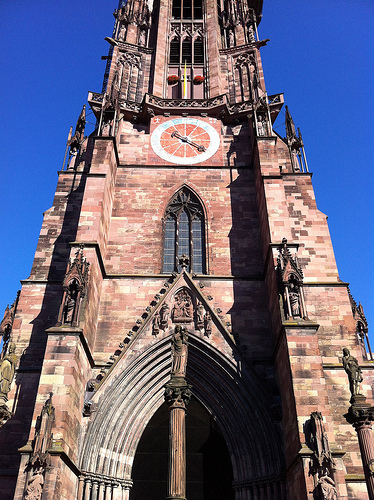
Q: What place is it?
A: It is a church.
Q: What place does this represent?
A: It represents the church.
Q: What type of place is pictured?
A: It is a church.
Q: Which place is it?
A: It is a church.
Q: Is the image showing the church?
A: Yes, it is showing the church.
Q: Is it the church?
A: Yes, it is the church.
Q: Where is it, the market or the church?
A: It is the church.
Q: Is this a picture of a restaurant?
A: No, the picture is showing a church.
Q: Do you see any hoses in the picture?
A: No, there are no hoses.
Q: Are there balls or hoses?
A: No, there are no hoses or balls.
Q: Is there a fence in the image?
A: No, there are no fences.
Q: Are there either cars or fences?
A: No, there are no fences or cars.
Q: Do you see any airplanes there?
A: No, there are no airplanes.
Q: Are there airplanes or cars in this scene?
A: No, there are no airplanes or cars.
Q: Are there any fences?
A: No, there are no fences.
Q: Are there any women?
A: Yes, there is a woman.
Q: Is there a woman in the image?
A: Yes, there is a woman.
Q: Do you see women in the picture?
A: Yes, there is a woman.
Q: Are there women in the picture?
A: Yes, there is a woman.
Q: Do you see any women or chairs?
A: Yes, there is a woman.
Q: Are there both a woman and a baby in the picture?
A: No, there is a woman but no babies.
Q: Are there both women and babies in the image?
A: No, there is a woman but no babies.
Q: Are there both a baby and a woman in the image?
A: No, there is a woman but no babies.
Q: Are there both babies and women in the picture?
A: No, there is a woman but no babies.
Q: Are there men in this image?
A: No, there are no men.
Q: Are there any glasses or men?
A: No, there are no men or glasses.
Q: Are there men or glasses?
A: No, there are no men or glasses.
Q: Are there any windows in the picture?
A: Yes, there is a window.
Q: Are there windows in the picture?
A: Yes, there is a window.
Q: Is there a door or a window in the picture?
A: Yes, there is a window.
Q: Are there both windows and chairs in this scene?
A: No, there is a window but no chairs.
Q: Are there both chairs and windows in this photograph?
A: No, there is a window but no chairs.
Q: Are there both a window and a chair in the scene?
A: No, there is a window but no chairs.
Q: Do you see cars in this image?
A: No, there are no cars.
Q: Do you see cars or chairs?
A: No, there are no cars or chairs.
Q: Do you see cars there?
A: No, there are no cars.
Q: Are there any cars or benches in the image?
A: No, there are no cars or benches.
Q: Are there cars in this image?
A: No, there are no cars.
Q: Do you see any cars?
A: No, there are no cars.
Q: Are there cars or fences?
A: No, there are no cars or fences.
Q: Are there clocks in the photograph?
A: Yes, there is a clock.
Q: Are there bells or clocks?
A: Yes, there is a clock.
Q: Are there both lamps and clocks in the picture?
A: No, there is a clock but no lamps.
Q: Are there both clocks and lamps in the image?
A: No, there is a clock but no lamps.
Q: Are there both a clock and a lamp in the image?
A: No, there is a clock but no lamps.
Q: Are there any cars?
A: No, there are no cars.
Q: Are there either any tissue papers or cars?
A: No, there are no cars or tissue papers.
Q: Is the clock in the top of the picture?
A: Yes, the clock is in the top of the image.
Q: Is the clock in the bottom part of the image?
A: No, the clock is in the top of the image.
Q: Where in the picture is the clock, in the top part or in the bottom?
A: The clock is in the top of the image.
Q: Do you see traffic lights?
A: No, there are no traffic lights.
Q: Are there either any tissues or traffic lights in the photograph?
A: No, there are no traffic lights or tissues.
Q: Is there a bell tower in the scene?
A: Yes, there is a bell tower.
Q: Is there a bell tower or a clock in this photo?
A: Yes, there is a bell tower.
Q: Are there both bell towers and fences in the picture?
A: No, there is a bell tower but no fences.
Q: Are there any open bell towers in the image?
A: Yes, there is an open bell tower.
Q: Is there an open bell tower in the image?
A: Yes, there is an open bell tower.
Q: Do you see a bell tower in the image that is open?
A: Yes, there is a bell tower that is open.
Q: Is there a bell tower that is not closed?
A: Yes, there is a open bell tower.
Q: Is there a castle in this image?
A: No, there are no castles.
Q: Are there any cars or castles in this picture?
A: No, there are no castles or cars.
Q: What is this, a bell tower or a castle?
A: This is a bell tower.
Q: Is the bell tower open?
A: Yes, the bell tower is open.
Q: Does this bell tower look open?
A: Yes, the bell tower is open.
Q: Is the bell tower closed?
A: No, the bell tower is open.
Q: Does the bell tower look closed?
A: No, the bell tower is open.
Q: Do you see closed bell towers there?
A: No, there is a bell tower but it is open.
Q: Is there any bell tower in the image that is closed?
A: No, there is a bell tower but it is open.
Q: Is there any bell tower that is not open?
A: No, there is a bell tower but it is open.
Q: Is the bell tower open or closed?
A: The bell tower is open.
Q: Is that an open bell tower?
A: Yes, that is an open bell tower.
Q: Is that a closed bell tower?
A: No, that is an open bell tower.